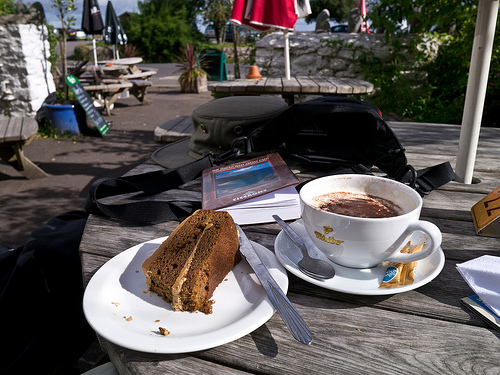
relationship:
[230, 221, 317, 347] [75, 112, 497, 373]
knife on table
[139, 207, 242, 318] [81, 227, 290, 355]
cake on plate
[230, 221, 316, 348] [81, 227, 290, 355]
knife on plate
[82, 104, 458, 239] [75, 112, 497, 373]
bag on table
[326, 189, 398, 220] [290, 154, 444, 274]
hot chocolate in cup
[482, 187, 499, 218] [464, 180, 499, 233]
number 22 on sign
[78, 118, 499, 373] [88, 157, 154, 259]
round tables outdoor tables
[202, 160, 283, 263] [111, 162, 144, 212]
book on table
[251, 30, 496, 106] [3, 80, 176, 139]
stone wall next to seating area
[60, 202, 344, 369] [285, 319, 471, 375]
plate on table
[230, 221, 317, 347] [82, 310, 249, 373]
knife on side of plate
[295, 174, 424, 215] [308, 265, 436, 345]
cup with coffee on a saucer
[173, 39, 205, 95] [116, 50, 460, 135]
plants on a patio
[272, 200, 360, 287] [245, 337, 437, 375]
spoon shadow on table